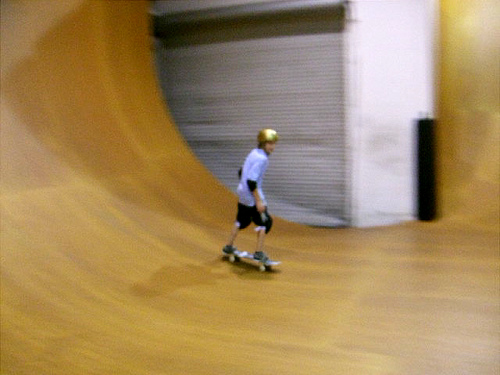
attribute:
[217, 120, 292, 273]
boy — skateboarding, moving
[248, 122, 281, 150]
helmet — gold, golden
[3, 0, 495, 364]
ramp — wooden, indoors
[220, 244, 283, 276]
skateboard — brown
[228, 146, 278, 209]
shirt — blue, black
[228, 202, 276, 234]
shorts — black, white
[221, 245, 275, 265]
sneakers — black, white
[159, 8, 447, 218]
wall — white dirty, white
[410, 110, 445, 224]
door — black, mettalic, grey, dark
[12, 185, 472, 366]
surface — curved, wooden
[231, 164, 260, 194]
elbow sleeves — black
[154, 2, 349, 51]
pipe — brown